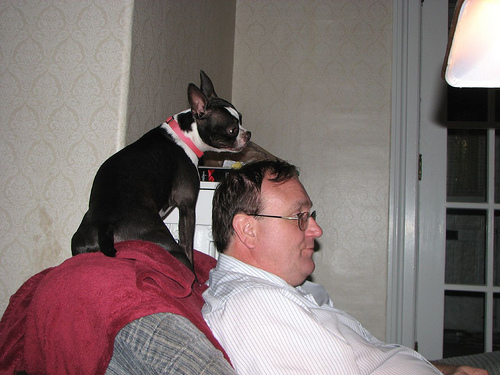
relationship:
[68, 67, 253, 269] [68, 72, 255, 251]
dog has fur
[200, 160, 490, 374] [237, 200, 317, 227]
man has glasses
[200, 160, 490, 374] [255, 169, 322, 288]
man has face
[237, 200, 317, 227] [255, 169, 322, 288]
glasses on face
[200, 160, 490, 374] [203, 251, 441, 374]
man wearing shirt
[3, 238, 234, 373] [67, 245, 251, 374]
blanket on chair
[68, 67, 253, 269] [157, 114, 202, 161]
dog wearing collar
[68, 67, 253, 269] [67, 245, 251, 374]
dog sitting on chair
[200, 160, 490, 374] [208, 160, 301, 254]
man has hair